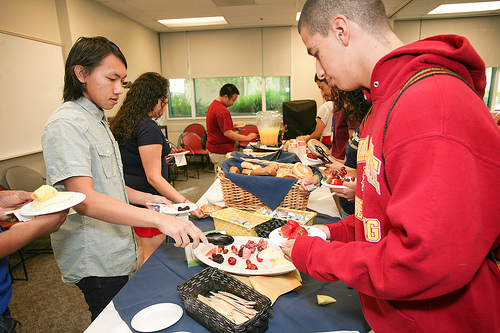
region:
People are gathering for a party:
[8, 7, 493, 325]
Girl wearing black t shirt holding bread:
[128, 68, 180, 221]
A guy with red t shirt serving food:
[285, 0, 499, 323]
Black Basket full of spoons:
[190, 275, 271, 330]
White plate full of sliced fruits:
[200, 225, 305, 283]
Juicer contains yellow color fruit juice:
[256, 110, 286, 147]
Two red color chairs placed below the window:
[180, 120, 208, 167]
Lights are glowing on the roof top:
[157, 2, 487, 53]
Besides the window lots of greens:
[166, 71, 291, 134]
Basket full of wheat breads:
[226, 148, 333, 218]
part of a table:
[317, 284, 328, 296]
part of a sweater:
[438, 189, 458, 226]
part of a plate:
[264, 248, 279, 270]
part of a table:
[165, 298, 178, 322]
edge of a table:
[153, 254, 165, 268]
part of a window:
[281, 82, 291, 84]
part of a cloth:
[279, 278, 286, 285]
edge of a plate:
[269, 263, 275, 278]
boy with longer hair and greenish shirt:
[44, 28, 157, 273]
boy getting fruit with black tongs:
[54, 37, 231, 289]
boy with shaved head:
[253, 2, 499, 319]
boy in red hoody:
[262, 3, 485, 313]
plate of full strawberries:
[269, 195, 331, 264]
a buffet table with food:
[187, 120, 331, 317]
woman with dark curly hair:
[118, 55, 217, 231]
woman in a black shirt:
[126, 70, 205, 219]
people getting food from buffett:
[283, 3, 480, 316]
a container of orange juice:
[251, 97, 287, 155]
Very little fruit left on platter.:
[187, 234, 307, 278]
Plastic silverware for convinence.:
[177, 288, 273, 329]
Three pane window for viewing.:
[160, 71, 298, 122]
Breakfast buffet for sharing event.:
[79, 108, 376, 331]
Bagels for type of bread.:
[209, 137, 337, 193]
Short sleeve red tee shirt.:
[199, 94, 245, 161]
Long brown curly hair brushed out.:
[107, 70, 177, 157]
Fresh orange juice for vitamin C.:
[251, 106, 288, 148]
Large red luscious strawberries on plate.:
[276, 216, 326, 244]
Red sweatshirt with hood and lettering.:
[282, 33, 499, 330]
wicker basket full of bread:
[224, 148, 324, 219]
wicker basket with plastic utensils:
[192, 278, 267, 330]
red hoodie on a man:
[330, 48, 472, 330]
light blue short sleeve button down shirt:
[41, 109, 135, 273]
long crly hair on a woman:
[122, 75, 149, 129]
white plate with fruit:
[195, 235, 276, 279]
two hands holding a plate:
[4, 188, 82, 250]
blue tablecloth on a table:
[130, 279, 154, 294]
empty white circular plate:
[127, 302, 191, 332]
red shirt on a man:
[211, 95, 236, 162]